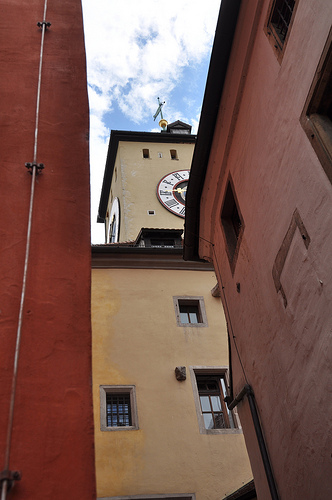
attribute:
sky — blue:
[83, 1, 222, 259]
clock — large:
[154, 166, 193, 218]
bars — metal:
[107, 394, 131, 425]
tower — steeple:
[85, 120, 198, 247]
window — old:
[278, 222, 314, 299]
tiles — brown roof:
[92, 239, 184, 248]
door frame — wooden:
[298, 25, 330, 188]